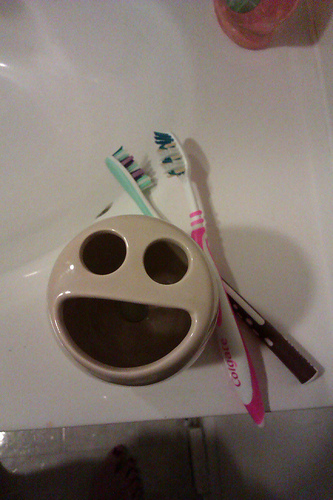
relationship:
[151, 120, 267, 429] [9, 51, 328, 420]
toothbrush on counter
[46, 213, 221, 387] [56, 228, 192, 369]
holder looks like face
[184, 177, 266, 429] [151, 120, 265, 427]
handle of toothbrush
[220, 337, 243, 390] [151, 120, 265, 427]
colgate manufactured toothbrush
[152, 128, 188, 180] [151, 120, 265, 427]
bristles on toothbrush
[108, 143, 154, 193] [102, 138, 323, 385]
bristles on brush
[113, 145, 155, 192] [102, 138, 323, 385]
purple bristle on brush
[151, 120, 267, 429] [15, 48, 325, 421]
toothbrush on sink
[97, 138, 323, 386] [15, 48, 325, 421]
brush on sink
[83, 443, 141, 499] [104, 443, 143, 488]
foot with toes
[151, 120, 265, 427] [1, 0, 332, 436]
toothbrush on counter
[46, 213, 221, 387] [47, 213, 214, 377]
holder looks like face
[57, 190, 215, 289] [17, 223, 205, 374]
holes of holder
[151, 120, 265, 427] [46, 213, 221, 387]
toothbrush next to holder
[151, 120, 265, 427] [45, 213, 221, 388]
toothbrush next to toothbrush holder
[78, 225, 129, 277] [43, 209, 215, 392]
holes in cup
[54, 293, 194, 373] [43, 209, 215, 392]
semi-circle in cup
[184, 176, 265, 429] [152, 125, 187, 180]
handle on brush